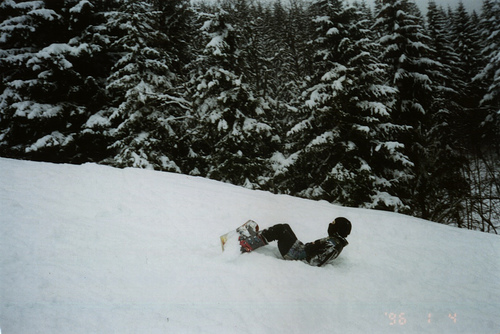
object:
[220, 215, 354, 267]
man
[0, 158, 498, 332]
snow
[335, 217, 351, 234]
hat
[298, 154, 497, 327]
hill side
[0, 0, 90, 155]
trees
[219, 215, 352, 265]
snowboarder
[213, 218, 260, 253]
board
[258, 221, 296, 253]
pants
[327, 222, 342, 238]
ski mask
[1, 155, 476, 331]
hill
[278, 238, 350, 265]
snow jacket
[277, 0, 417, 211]
tree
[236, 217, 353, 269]
skier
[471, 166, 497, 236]
branches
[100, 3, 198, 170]
evergreen trees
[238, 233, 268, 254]
boots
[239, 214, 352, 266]
person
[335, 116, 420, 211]
snow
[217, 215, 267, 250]
skis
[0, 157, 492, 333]
slope